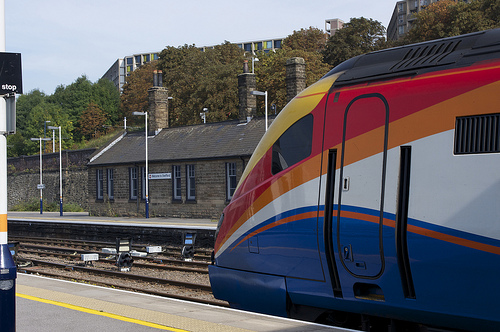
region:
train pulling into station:
[207, 42, 497, 313]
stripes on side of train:
[221, 86, 497, 268]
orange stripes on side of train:
[236, 81, 498, 271]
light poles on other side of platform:
[12, 80, 270, 220]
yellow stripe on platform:
[15, 282, 186, 329]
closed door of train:
[330, 96, 385, 275]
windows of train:
[270, 115, 499, 179]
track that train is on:
[12, 214, 214, 296]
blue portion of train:
[212, 213, 498, 316]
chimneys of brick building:
[140, 59, 337, 117]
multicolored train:
[195, 41, 498, 321]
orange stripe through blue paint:
[234, 205, 496, 319]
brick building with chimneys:
[94, 69, 316, 221]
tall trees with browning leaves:
[130, 42, 313, 114]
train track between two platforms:
[15, 206, 205, 329]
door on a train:
[331, 83, 403, 284]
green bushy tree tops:
[16, 71, 116, 154]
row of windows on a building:
[88, 165, 249, 207]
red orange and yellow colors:
[226, 48, 494, 219]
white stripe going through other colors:
[234, 109, 494, 249]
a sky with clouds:
[2, 2, 417, 82]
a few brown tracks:
[7, 218, 238, 318]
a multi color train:
[207, 22, 497, 330]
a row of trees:
[10, 9, 498, 129]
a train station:
[21, 128, 252, 235]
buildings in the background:
[79, 3, 494, 123]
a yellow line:
[12, 278, 195, 330]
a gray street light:
[124, 96, 165, 228]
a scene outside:
[4, 5, 499, 326]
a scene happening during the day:
[4, 4, 499, 310]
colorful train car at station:
[55, 25, 488, 315]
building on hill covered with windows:
[100, 45, 305, 115]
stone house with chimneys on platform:
[81, 55, 306, 215]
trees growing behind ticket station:
[20, 50, 265, 145]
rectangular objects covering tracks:
[77, 230, 193, 265]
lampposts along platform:
[25, 81, 270, 208]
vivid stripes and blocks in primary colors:
[205, 45, 487, 320]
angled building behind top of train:
[382, 1, 432, 42]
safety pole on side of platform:
[0, 5, 16, 325]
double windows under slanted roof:
[88, 122, 239, 202]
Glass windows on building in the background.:
[117, 50, 143, 77]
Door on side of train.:
[332, 88, 386, 295]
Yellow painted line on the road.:
[15, 268, 167, 330]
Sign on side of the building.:
[144, 159, 174, 191]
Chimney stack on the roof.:
[143, 63, 174, 150]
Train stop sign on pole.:
[1, 43, 28, 108]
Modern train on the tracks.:
[200, 32, 498, 326]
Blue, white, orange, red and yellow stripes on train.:
[219, 70, 462, 324]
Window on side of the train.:
[262, 111, 317, 178]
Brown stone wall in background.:
[22, 164, 84, 199]